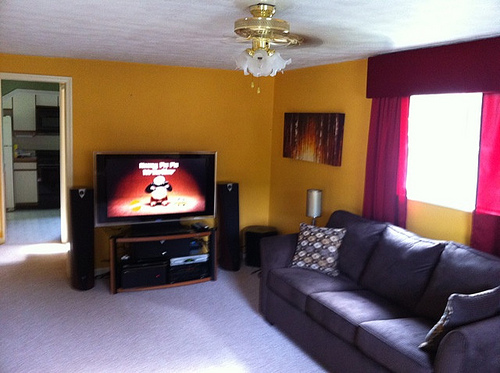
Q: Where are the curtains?
A: On the window.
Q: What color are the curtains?
A: Pink.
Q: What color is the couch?
A: Purple.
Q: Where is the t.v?
A: On stand.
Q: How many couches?
A: One.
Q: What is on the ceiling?
A: Fan.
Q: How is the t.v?
A: On.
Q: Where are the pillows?
A: On couch.